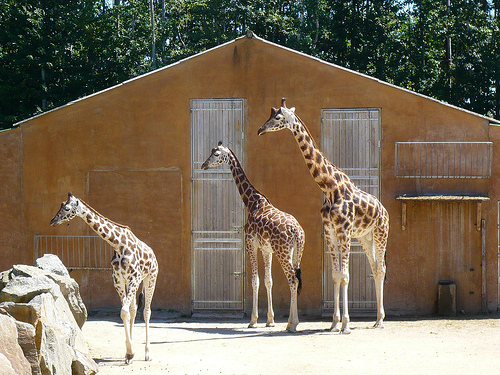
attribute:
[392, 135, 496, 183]
railing — metal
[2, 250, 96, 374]
pile — boulders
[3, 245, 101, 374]
rocks — large, here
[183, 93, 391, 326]
two doors — tall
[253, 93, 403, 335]
male giraffe — lightly colored, large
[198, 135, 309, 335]
female giraffe — darkly colored, medium sized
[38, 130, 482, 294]
wall — here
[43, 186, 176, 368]
giraffe — here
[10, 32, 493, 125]
roof — here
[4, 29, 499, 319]
house — here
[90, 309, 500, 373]
ground — here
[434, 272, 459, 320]
box — small